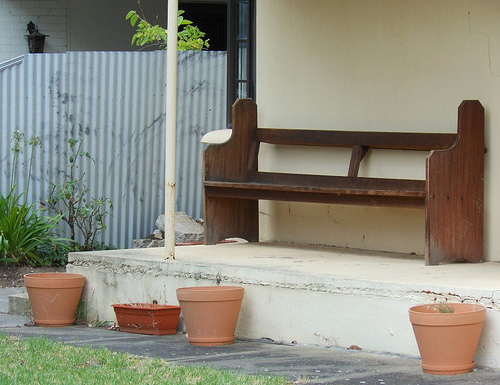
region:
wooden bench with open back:
[196, 96, 496, 266]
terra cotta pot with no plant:
[174, 277, 254, 351]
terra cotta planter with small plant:
[403, 296, 497, 377]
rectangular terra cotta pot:
[106, 292, 180, 344]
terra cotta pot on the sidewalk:
[18, 263, 88, 338]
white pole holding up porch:
[153, 7, 194, 261]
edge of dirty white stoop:
[61, 241, 204, 285]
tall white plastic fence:
[52, 38, 138, 210]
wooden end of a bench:
[422, 80, 497, 272]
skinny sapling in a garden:
[41, 67, 88, 250]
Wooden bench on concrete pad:
[201, 97, 484, 264]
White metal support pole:
[154, 3, 188, 258]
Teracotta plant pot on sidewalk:
[403, 298, 484, 373]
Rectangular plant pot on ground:
[113, 301, 182, 338]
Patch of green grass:
[5, 338, 287, 383]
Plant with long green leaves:
[5, 185, 71, 270]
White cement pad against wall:
[65, 225, 496, 356]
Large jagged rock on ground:
[136, 208, 209, 249]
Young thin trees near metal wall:
[42, 113, 107, 253]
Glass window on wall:
[224, 3, 253, 105]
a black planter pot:
[23, 19, 64, 58]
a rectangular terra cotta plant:
[97, 291, 202, 351]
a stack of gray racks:
[152, 206, 217, 263]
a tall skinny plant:
[29, 129, 127, 245]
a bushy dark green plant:
[6, 185, 67, 275]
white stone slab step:
[287, 240, 376, 345]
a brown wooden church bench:
[219, 108, 496, 283]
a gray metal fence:
[50, 58, 161, 218]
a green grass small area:
[30, 343, 77, 369]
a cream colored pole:
[155, 4, 189, 241]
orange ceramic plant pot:
[168, 273, 249, 351]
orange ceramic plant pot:
[403, 297, 478, 375]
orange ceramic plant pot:
[14, 265, 86, 332]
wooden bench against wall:
[201, 87, 488, 266]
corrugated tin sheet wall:
[104, 50, 153, 218]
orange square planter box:
[108, 295, 178, 340]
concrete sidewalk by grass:
[283, 336, 354, 376]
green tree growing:
[57, 141, 95, 241]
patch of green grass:
[32, 342, 119, 377]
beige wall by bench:
[293, 57, 377, 108]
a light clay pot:
[410, 302, 488, 372]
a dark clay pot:
[112, 301, 180, 336]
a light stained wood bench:
[204, 98, 489, 265]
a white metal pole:
[167, 1, 174, 258]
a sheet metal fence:
[2, 49, 226, 259]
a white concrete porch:
[67, 241, 498, 371]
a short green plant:
[0, 189, 68, 267]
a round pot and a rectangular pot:
[110, 282, 248, 344]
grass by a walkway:
[1, 331, 284, 381]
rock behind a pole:
[154, 211, 201, 235]